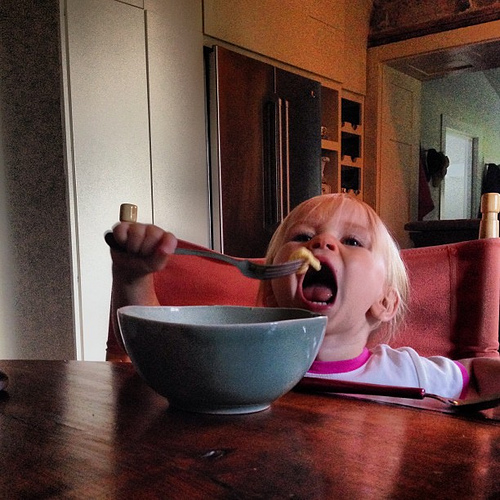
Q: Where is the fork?
A: In the hand.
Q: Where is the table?
A: Under the bowl.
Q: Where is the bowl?
A: On the table.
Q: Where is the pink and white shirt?
A: On the baby.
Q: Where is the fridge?
A: Behind the child.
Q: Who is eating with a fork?
A: A child.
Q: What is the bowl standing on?
A: Table.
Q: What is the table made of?
A: Wood.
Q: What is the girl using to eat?
A: Fork.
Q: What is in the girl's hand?
A: Fork.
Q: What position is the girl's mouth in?
A: Open.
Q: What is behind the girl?
A: Back of chair.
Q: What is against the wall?
A: Fridge.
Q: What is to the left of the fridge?
A: Pantry.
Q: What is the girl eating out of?
A: Bowl.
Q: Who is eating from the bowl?
A: A little boy.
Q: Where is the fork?
A: The fork is in the boy's right hand.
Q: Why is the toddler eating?
A: He appears to be hungry.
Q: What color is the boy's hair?
A: Blonde.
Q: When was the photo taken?
A: Daylight hours.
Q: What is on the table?
A: A shiny blue bowl.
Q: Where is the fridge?
A: Behind the child.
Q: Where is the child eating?
A: Near a dark brown table.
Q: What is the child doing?
A: Eating.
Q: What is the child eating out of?
A: Bowl.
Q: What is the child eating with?
A: Fork.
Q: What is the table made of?
A: Wood.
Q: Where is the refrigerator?
A: Behind the child.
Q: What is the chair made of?
A: Wood and cloth.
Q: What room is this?
A: Kitchen.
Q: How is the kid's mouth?
A: Open.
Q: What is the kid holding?
A: A fork.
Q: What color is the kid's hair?
A: Blond.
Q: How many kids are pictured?
A: One.